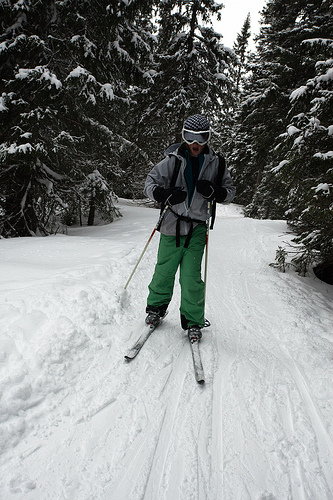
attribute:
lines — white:
[271, 330, 328, 484]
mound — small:
[0, 270, 86, 430]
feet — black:
[146, 305, 204, 341]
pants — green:
[144, 224, 210, 325]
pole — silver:
[116, 203, 174, 295]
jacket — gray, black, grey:
[146, 149, 238, 233]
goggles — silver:
[177, 126, 211, 148]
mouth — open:
[190, 144, 203, 156]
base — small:
[79, 200, 100, 228]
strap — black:
[166, 211, 210, 247]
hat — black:
[183, 113, 210, 131]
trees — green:
[3, 4, 329, 229]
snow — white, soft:
[23, 390, 315, 496]